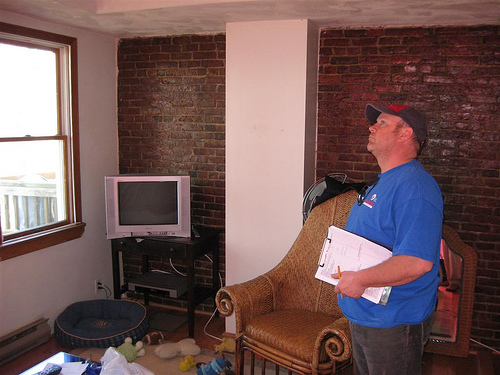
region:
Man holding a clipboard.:
[305, 88, 459, 370]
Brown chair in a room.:
[215, 181, 404, 371]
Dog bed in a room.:
[50, 295, 147, 350]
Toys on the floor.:
[137, 328, 231, 373]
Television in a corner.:
[97, 170, 195, 244]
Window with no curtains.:
[2, 18, 89, 263]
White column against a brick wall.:
[215, 15, 314, 331]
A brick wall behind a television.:
[118, 35, 223, 292]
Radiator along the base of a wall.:
[2, 310, 52, 366]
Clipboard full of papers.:
[312, 223, 397, 313]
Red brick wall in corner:
[115, 36, 222, 176]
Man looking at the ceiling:
[315, 106, 445, 327]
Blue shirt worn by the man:
[332, 160, 438, 326]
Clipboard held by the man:
[315, 222, 391, 302]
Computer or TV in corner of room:
[101, 175, 191, 240]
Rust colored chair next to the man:
[213, 186, 363, 369]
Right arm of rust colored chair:
[211, 271, 286, 316]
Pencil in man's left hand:
[332, 262, 345, 298]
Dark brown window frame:
[0, 18, 86, 259]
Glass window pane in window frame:
[2, 45, 71, 237]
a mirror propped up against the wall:
[408, 210, 485, 366]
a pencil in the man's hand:
[334, 263, 343, 300]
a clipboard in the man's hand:
[308, 217, 396, 311]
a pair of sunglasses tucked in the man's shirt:
[348, 168, 382, 213]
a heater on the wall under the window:
[1, 313, 55, 368]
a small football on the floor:
[137, 325, 172, 351]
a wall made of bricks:
[325, 46, 495, 103]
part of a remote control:
[31, 353, 64, 374]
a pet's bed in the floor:
[47, 294, 157, 351]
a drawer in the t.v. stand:
[107, 234, 189, 263]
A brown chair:
[211, 181, 398, 372]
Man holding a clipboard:
[312, 91, 440, 372]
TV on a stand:
[94, 165, 216, 340]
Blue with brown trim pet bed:
[51, 291, 151, 355]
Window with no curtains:
[0, 7, 90, 267]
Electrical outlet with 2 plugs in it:
[88, 271, 111, 303]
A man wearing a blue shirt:
[308, 91, 455, 373]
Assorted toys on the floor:
[107, 323, 240, 373]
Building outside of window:
[1, 182, 66, 239]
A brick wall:
[107, 24, 498, 341]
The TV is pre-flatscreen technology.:
[98, 168, 197, 242]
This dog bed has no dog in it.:
[51, 290, 152, 351]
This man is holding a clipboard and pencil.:
[311, 96, 451, 373]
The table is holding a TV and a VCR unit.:
[98, 165, 223, 341]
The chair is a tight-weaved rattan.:
[208, 175, 365, 373]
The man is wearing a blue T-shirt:
[333, 90, 450, 371]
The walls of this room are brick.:
[113, 32, 358, 155]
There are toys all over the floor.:
[108, 316, 238, 372]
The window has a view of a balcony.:
[3, 15, 94, 260]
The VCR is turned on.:
[126, 262, 194, 303]